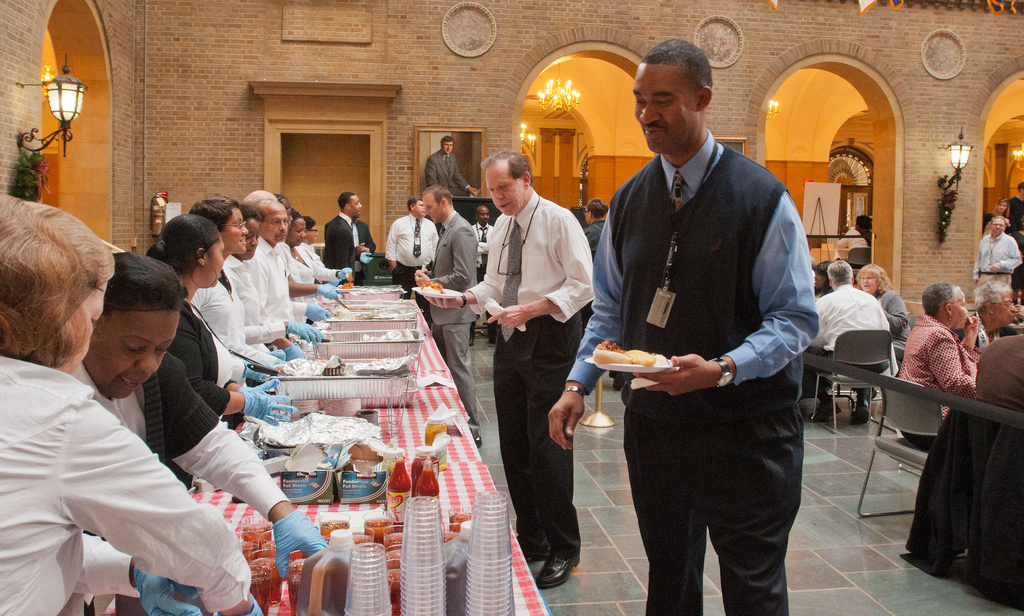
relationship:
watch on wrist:
[719, 355, 736, 379] [700, 361, 741, 399]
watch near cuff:
[719, 355, 736, 379] [730, 345, 770, 386]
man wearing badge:
[549, 47, 815, 609] [644, 286, 674, 328]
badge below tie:
[644, 286, 674, 328] [671, 170, 688, 214]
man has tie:
[549, 47, 815, 609] [671, 170, 688, 214]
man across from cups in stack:
[549, 47, 815, 609] [342, 499, 516, 611]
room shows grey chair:
[2, 2, 1024, 614] [810, 332, 891, 425]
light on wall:
[21, 70, 85, 156] [0, 9, 41, 161]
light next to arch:
[21, 70, 85, 156] [45, 8, 121, 247]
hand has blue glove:
[275, 508, 322, 585] [273, 520, 314, 591]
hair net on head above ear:
[161, 217, 216, 275] [195, 250, 214, 272]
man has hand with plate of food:
[549, 47, 815, 609] [589, 345, 677, 381]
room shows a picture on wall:
[2, 2, 1024, 614] [802, 180, 848, 241]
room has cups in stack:
[2, 2, 1024, 614] [342, 499, 516, 611]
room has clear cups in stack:
[2, 2, 1024, 614] [342, 499, 516, 611]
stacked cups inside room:
[342, 499, 516, 611] [2, 2, 1024, 614]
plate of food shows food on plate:
[589, 345, 677, 381] [651, 355, 675, 379]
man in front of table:
[549, 47, 815, 609] [296, 287, 538, 608]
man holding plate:
[549, 47, 815, 609] [651, 355, 675, 379]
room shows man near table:
[2, 2, 1024, 614] [296, 287, 538, 608]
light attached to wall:
[21, 70, 85, 156] [0, 9, 41, 161]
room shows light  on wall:
[2, 2, 1024, 614] [0, 9, 41, 161]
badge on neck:
[644, 286, 674, 328] [663, 143, 715, 164]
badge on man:
[644, 286, 674, 328] [549, 47, 815, 609]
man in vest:
[549, 47, 815, 609] [609, 172, 789, 415]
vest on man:
[609, 172, 789, 415] [549, 47, 815, 609]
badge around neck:
[644, 286, 674, 328] [663, 143, 715, 164]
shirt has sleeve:
[570, 154, 829, 376] [737, 200, 819, 376]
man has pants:
[549, 47, 815, 609] [619, 393, 810, 611]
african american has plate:
[549, 47, 815, 609] [651, 355, 675, 379]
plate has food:
[651, 355, 675, 379] [593, 343, 650, 370]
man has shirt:
[422, 149, 614, 598] [468, 208, 591, 317]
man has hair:
[422, 149, 614, 598] [483, 159, 532, 182]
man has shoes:
[422, 149, 614, 598] [527, 545, 573, 589]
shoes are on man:
[527, 545, 573, 589] [422, 149, 614, 598]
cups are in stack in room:
[403, 504, 450, 614] [2, 2, 1024, 614]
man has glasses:
[422, 149, 614, 598] [495, 206, 545, 278]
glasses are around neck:
[495, 206, 545, 278] [519, 190, 537, 222]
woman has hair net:
[159, 209, 227, 382] [161, 217, 216, 275]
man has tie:
[422, 149, 614, 598] [506, 219, 527, 306]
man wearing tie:
[422, 149, 614, 598] [506, 219, 527, 306]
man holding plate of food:
[549, 47, 815, 609] [589, 345, 677, 381]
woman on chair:
[904, 280, 988, 393] [857, 378, 935, 514]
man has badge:
[549, 47, 815, 609] [644, 286, 674, 328]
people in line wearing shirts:
[11, 193, 331, 605] [2, 246, 324, 613]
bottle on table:
[386, 465, 403, 526] [296, 287, 538, 608]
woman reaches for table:
[97, 258, 285, 526] [296, 287, 538, 608]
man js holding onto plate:
[549, 47, 815, 609] [651, 355, 675, 379]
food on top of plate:
[593, 343, 650, 370] [651, 355, 675, 379]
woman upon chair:
[904, 280, 988, 393] [857, 378, 935, 514]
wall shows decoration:
[0, 9, 41, 161] [439, 14, 505, 66]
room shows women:
[2, 2, 1024, 614] [5, 217, 322, 611]